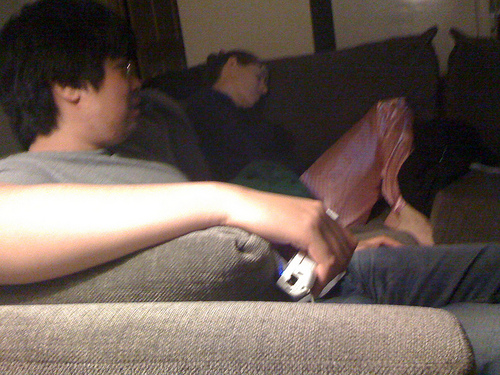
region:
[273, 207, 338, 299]
White wii remote.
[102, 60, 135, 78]
Small framed glasses on a man's face.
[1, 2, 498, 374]
Asian man sitting on a couch.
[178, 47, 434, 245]
A sleeping nwoman with pink pants.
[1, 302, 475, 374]
The long arm of a grey couch.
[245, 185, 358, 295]
Right hand of an Asian man.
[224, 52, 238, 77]
A woman's right ear.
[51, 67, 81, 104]
A man's right ear.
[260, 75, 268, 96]
Nose on a woman's face.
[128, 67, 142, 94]
Nose on a man's face.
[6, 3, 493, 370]
two people on the couch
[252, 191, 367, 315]
fingers wrapped around a wii controller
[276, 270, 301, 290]
plug on the bottom of the controller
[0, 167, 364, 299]
arm resting on the pillow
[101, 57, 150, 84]
glasses on the face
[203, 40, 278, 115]
head leaning to the side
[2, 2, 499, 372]
man holding a wii controller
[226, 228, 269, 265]
corner of the pillow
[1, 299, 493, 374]
armrest on the couch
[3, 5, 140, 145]
dark hair on the head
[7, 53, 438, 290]
people sitting on couch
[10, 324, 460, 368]
arm of the couch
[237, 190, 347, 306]
controller in the hand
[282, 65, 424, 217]
pants of the woman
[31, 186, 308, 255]
arm of the man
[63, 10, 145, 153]
head of the man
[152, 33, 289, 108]
head of the woman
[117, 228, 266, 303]
cushion of the cocuh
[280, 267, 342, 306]
the controller is white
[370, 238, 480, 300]
the jeans are blue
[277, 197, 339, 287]
white remote the man is holding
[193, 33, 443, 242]
woman laying on the couch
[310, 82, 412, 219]
pink pants the woman is wearing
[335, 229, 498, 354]
jeans the man is wearing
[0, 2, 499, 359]
man sitting on the couch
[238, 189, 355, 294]
hand holding the controller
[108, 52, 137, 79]
glasses the man is wearing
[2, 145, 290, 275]
gray shirt the man is wearing